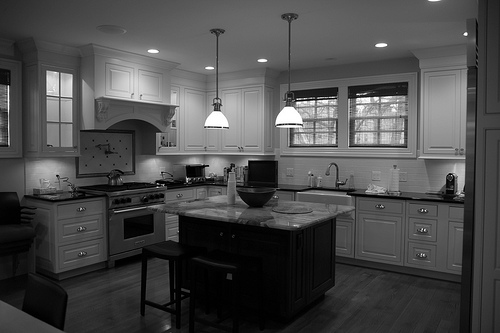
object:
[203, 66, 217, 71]
light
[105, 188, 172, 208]
range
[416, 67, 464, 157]
cupboard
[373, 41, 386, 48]
light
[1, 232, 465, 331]
hardwood floor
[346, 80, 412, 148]
windows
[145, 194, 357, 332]
island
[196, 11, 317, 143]
surfboard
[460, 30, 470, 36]
light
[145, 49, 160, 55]
light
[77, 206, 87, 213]
knob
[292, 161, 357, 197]
sink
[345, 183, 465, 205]
counters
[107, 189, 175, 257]
oven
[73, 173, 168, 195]
stovetop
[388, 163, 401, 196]
towels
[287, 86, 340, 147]
window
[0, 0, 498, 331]
kitchen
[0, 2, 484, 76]
ceiling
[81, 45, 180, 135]
stove fan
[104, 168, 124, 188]
kettle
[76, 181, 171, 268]
stove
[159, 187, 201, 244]
cabinet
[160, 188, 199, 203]
drawer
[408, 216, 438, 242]
drawer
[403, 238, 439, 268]
drawer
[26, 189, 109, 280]
cabinet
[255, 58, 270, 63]
light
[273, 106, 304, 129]
light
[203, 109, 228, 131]
light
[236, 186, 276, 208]
bowl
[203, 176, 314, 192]
counter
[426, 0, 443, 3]
light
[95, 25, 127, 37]
light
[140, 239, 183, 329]
chair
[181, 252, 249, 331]
chair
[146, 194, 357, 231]
bar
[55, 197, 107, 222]
drawer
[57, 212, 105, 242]
drawer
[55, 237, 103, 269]
drawer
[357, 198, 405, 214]
drawer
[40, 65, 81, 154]
window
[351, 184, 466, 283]
island